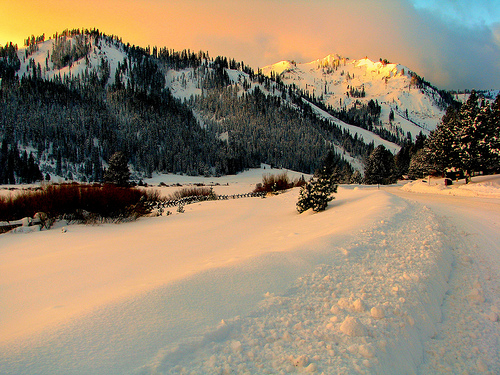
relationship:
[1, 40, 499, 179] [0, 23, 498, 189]
trees on mountains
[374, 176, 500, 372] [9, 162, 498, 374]
pathway on ground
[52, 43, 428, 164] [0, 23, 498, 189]
snow on mountains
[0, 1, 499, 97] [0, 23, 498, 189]
sky above mountains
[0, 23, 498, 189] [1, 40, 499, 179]
mountains underneath trees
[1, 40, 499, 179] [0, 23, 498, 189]
trees on top of mountains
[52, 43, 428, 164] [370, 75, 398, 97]
snow colored white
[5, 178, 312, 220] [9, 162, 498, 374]
bushes on ground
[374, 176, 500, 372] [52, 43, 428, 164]
pathway in snow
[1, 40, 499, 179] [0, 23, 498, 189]
trees cover mountains